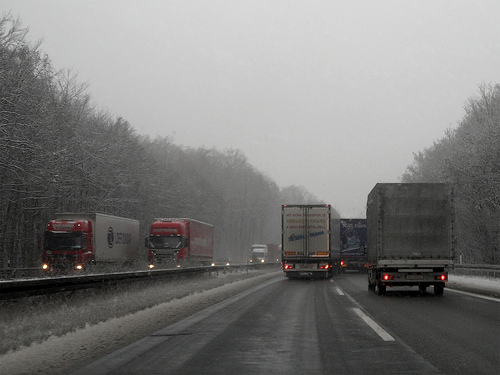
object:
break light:
[284, 264, 289, 269]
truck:
[279, 202, 343, 281]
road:
[0, 260, 500, 374]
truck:
[365, 180, 455, 295]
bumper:
[377, 257, 454, 284]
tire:
[376, 280, 386, 296]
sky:
[0, 0, 500, 220]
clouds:
[284, 71, 294, 77]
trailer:
[92, 212, 141, 263]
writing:
[107, 226, 132, 249]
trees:
[0, 42, 9, 279]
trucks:
[41, 211, 142, 277]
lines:
[351, 306, 397, 343]